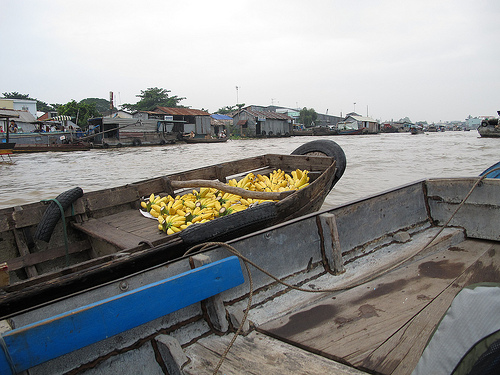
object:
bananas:
[141, 167, 314, 237]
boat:
[1, 152, 340, 315]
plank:
[0, 255, 243, 375]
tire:
[290, 138, 347, 184]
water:
[343, 133, 435, 172]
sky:
[0, 0, 497, 104]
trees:
[54, 87, 191, 115]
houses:
[0, 107, 293, 147]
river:
[13, 132, 500, 178]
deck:
[339, 233, 500, 374]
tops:
[218, 206, 233, 217]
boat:
[410, 125, 424, 135]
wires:
[182, 242, 284, 287]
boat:
[0, 177, 500, 375]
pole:
[168, 178, 295, 200]